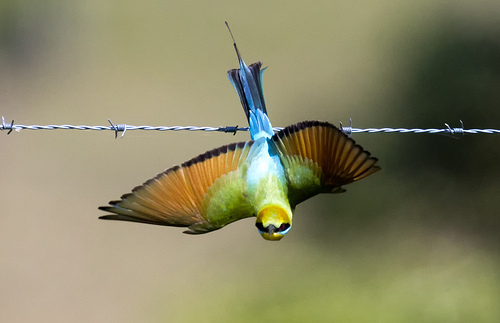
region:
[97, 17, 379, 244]
upside down bird on a wire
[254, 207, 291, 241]
yellow head of bird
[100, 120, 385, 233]
orange and green wings on bird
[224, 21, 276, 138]
blue tail on bird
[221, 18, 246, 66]
pointed end of tail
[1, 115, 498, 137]
barbed wire that bird is hanging from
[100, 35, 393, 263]
Small bird caught on a wite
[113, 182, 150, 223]
Orange and black feathers on a bird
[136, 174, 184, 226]
Orange and black feathers on a bird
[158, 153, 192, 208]
Orange and black feathers on a bird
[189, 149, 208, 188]
Orange and black feathers on a bird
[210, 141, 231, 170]
Orange and black feathers on a bird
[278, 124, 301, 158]
Orange and black feathers on a bird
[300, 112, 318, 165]
Orange and black feathers on a bird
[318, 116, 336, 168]
Orange and black feathers on a bird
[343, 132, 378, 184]
Orange and black feathers on a bird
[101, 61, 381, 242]
colorful bird on the wire fence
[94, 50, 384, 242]
blue bird on the fence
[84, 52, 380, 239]
orange bird on the fence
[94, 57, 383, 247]
black bird on the fence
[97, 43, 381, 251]
yellow bird on the fence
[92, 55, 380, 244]
green bird on the fence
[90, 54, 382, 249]
purple bird on the fence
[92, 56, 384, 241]
bird is upside down on the fence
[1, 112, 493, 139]
sharp wire barbs on the fence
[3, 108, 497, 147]
silver barbs on the fence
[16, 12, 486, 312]
bird hanging upside down from barbed wire fence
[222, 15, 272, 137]
long and short blue feathers on tail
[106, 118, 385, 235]
orange wings edged in black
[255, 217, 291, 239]
dark band on both sides of beak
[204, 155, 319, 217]
short green feathers between body and wings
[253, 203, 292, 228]
orange semicircle around head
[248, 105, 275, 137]
pointed blue feathers in a row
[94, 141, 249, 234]
connected feathers creating a fan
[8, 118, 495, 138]
twisted blue wire pulled taut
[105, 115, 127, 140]
pointed projections from wire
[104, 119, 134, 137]
metal barbs on wire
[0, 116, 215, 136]
silver barb wire fencing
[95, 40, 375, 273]
multi-coloured bird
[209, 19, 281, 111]
blue and black tail feathers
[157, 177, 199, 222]
orange feathers on bird wing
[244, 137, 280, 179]
blue feathers on bird breast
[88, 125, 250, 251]
extended wing on bird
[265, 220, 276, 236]
brown beak on bird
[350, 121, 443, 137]
silver metal bard-wire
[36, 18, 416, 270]
flying multi-coloured bird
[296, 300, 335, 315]
man surfing on a white surfboardman surfing on a white surfboardman surfing on a white surfboard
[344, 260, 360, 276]
man surfing on a white surfboardman surfing on a white surfboardman surfing on a white surfboard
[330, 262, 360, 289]
man surfing on a white surfboardman surfing on a white surfboardman surfing on a white surfboard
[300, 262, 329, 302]
man surfing on a white surfboardman surfing on a white surfboardman surfing on a white surfboard